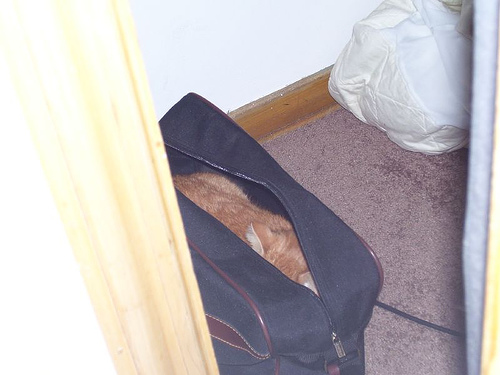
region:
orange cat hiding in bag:
[168, 142, 333, 301]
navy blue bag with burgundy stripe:
[151, 95, 400, 359]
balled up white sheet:
[330, 3, 475, 167]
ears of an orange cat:
[240, 218, 328, 295]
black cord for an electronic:
[370, 300, 457, 357]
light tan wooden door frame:
[42, 55, 221, 361]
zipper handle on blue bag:
[323, 325, 365, 357]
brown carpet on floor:
[287, 143, 461, 243]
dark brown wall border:
[212, 60, 357, 145]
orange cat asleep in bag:
[157, 152, 343, 311]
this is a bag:
[178, 110, 373, 372]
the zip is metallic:
[325, 326, 349, 350]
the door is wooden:
[87, 87, 138, 164]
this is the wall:
[196, 25, 271, 67]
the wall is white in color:
[210, 10, 300, 69]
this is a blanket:
[353, 44, 395, 89]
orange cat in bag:
[167, 120, 308, 303]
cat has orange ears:
[231, 228, 287, 259]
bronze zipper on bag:
[308, 325, 346, 346]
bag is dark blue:
[122, 107, 369, 334]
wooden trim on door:
[46, 37, 212, 367]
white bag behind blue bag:
[335, 16, 466, 148]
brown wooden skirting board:
[233, 59, 317, 139]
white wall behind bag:
[184, 0, 259, 96]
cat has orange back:
[181, 165, 239, 228]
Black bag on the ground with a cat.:
[269, 142, 297, 290]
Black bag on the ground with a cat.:
[127, 157, 204, 187]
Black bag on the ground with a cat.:
[289, 293, 320, 323]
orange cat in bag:
[150, 165, 315, 292]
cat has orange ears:
[237, 238, 339, 296]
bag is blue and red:
[143, 131, 383, 350]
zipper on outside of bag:
[325, 320, 353, 367]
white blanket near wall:
[354, 2, 481, 176]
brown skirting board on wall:
[242, 47, 344, 159]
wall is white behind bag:
[160, 0, 255, 101]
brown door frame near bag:
[20, 16, 220, 343]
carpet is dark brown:
[277, 129, 433, 239]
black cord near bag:
[359, 297, 498, 369]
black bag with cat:
[126, 88, 397, 373]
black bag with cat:
[137, 83, 387, 370]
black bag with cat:
[140, 69, 392, 365]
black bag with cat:
[130, 83, 395, 371]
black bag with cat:
[137, 79, 399, 371]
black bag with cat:
[134, 79, 394, 373]